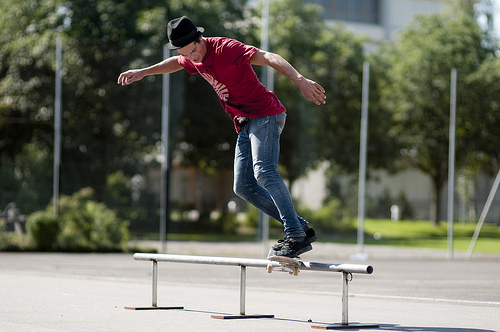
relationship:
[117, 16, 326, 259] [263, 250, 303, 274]
male performing trick on a skateboard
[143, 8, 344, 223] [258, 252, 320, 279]
male on skateboard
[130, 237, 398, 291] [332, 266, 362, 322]
tube on stand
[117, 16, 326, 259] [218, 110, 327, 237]
male wearing blue jeans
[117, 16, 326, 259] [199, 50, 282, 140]
male wearing shirt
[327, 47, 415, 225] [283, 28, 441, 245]
metal pole in park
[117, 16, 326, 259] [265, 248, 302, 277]
male standing on skateboard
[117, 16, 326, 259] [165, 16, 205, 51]
male wearing black hat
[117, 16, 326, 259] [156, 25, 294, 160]
male wearing shirt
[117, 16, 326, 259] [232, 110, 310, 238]
male wearing blue blue jeans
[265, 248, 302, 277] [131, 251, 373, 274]
skateboard on top of ramp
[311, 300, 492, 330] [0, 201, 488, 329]
shadow of man on ground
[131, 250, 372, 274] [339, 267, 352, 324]
pole supporting big pole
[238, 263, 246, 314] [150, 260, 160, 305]
pole supporting big pole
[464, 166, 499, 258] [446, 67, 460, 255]
pole supporting big pole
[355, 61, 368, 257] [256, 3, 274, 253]
metal pole supporting big pole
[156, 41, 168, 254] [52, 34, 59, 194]
pole supporting big pole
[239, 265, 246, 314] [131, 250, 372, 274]
pole supporting big pole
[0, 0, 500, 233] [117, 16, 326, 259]
tree behind male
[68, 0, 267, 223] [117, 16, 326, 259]
tree behind male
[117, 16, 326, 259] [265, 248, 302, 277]
male balancing skateboard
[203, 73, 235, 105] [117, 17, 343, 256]
design on mans red shirt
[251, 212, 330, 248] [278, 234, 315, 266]
black shoes on man's feet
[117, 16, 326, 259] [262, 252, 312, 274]
male riding skateboard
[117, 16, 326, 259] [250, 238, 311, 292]
male riding skateboard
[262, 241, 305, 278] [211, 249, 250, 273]
skateboard sitting on top of pole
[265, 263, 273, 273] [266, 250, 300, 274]
wheel under skateboard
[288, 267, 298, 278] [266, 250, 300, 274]
wheel under skateboard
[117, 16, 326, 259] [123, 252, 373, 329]
male balancing board on metal rail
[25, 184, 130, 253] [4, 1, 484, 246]
bush in background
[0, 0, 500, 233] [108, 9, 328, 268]
tree behind boarder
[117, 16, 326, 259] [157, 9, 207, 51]
male wearing black hat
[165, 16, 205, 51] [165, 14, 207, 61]
black hat on top of mans head